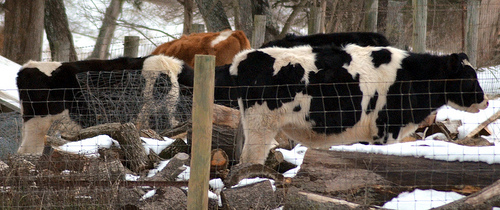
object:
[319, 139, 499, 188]
log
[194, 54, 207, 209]
fence pole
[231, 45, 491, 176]
cow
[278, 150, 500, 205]
terrain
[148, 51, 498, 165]
closure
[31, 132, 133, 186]
tree stump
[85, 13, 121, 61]
trees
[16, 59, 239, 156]
cow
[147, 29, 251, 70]
cows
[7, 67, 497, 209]
fence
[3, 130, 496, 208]
ground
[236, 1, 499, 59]
wall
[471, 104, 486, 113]
mouth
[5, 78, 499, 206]
chicken wire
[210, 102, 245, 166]
log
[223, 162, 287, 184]
log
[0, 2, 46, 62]
tree trunk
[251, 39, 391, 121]
spots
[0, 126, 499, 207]
snow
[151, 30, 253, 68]
brown cow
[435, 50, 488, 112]
head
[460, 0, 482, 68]
trees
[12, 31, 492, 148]
group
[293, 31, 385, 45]
back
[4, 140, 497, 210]
field